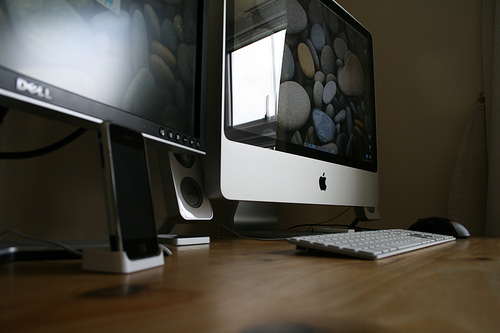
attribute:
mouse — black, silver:
[405, 215, 473, 237]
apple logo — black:
[318, 171, 327, 189]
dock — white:
[93, 248, 166, 273]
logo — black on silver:
[314, 172, 328, 195]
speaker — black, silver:
[145, 136, 219, 251]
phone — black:
[91, 117, 169, 272]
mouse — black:
[432, 206, 476, 245]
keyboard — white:
[281, 227, 456, 258]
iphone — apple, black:
[95, 98, 185, 267]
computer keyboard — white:
[281, 210, 471, 280]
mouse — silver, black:
[408, 214, 473, 239]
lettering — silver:
[13, 77, 54, 104]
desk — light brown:
[2, 226, 498, 331]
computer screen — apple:
[197, 0, 374, 206]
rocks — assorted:
[264, 44, 351, 129]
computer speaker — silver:
[108, 124, 174, 276]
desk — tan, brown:
[246, 255, 346, 307]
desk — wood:
[171, 204, 496, 331]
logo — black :
[305, 170, 337, 193]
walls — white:
[1, 1, 483, 240]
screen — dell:
[63, 25, 190, 127]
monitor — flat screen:
[220, 0, 381, 214]